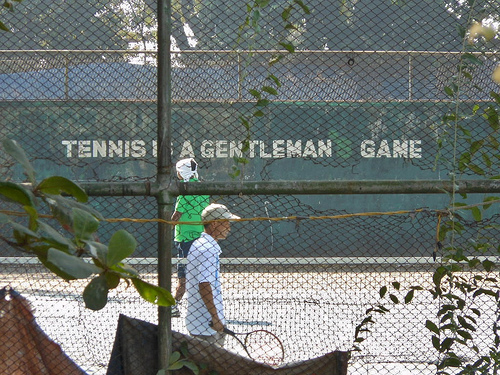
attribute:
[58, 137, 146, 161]
letters — white, tennis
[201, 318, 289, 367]
racket — tennis, black, red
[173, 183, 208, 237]
shirt — green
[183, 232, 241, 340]
shirt — white, collared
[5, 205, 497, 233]
cord — electric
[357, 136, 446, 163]
letters — white, game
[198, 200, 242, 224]
cap — bright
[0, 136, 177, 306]
leaves — green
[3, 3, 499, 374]
fence — metal, chain link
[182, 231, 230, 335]
shirt — white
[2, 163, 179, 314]
leaves — large, green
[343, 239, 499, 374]
branches — thin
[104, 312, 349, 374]
tarp — brown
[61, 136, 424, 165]
letters — large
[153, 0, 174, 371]
pole — old, metal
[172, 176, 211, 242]
shirt — green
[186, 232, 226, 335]
shirt — white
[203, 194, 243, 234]
cap — tan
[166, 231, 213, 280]
shorts — blue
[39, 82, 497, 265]
wall — tall, green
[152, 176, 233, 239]
shirt — green